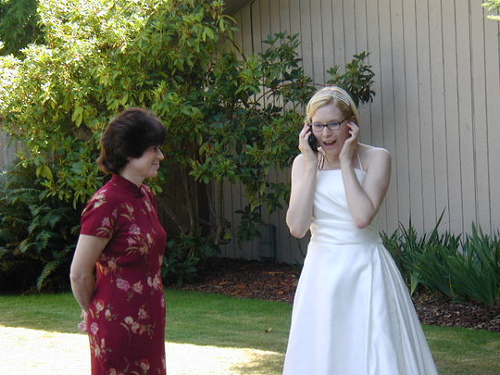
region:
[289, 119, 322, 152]
small black cell phone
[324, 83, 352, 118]
part in blond hair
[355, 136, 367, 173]
strap on white dress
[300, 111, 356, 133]
pair of eye glasses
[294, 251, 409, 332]
long silk white dress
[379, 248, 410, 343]
pleats in white dress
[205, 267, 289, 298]
leaves on the ground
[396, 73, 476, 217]
tall brown fence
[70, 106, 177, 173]
woman with short black hair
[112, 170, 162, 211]
collar on red dress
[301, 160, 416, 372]
the wedding dress is white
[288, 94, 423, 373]
the woman is on the phone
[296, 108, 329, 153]
the phone is black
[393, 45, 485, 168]
the fence is wooden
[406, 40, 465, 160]
the fence is white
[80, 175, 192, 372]
the dress is red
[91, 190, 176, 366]
flowers are on the dress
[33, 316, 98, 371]
suns reflection is on the grass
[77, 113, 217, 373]
the woman has hands folded behind her back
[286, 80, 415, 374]
she is smiling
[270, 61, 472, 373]
a young blonde bride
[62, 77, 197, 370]
lady wearing a burgandy dress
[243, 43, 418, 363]
bride talking on the phone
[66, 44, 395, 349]
lady watching bride talk on phone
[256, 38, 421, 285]
bride excited to talk to someone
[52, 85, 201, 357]
bride's mother with hands behind her back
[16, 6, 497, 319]
shrubbery against building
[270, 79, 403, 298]
bride with a sleeveless white dress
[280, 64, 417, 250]
bride covering ear trying to hear person on phone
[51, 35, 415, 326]
mother happily watching her daughter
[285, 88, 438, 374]
young woman in white dress on cell phone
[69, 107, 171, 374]
woman with black hair wearing oriental style dress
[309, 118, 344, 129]
pair of eyeglasses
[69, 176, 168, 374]
maroon dress with flower pattern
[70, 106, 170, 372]
woman smiling with hands behind back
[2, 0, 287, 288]
stand of bamboo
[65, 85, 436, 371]
two women in yard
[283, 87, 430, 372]
woman in white dress on cell phone covering other ear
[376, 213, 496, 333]
garden plants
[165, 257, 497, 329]
garden strip covered with mulch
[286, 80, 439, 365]
the girl in the white dress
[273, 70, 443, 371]
the girl on the phone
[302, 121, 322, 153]
the phone up to the girls ear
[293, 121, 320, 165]
the phone in the girls hand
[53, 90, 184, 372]
the women stands with her arms behind her back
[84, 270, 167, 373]
the flower print on the dress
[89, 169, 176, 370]
the red dress of the women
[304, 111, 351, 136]
the glasses on the girls face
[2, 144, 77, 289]
the bushes by the house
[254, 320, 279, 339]
the leaf on the mowed lawn